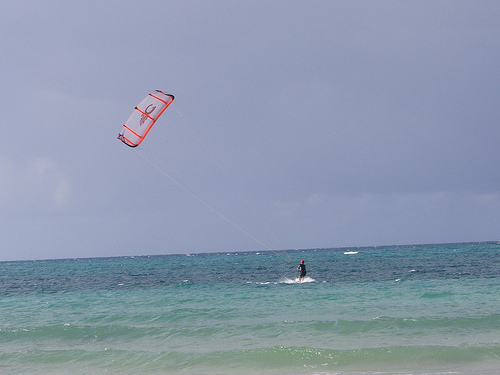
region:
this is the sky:
[41, 133, 86, 211]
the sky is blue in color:
[278, 88, 425, 167]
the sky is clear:
[236, 94, 470, 212]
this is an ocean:
[55, 255, 203, 356]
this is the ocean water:
[100, 260, 180, 280]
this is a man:
[290, 255, 315, 285]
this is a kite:
[110, 82, 176, 152]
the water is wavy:
[156, 290, 248, 350]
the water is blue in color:
[103, 262, 176, 287]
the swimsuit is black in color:
[300, 263, 305, 278]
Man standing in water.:
[298, 261, 306, 277]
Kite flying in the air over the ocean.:
[115, 88, 176, 150]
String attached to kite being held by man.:
[136, 146, 299, 276]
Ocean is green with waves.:
[37, 291, 494, 373]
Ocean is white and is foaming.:
[279, 277, 313, 282]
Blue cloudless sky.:
[222, 40, 449, 209]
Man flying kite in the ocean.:
[117, 87, 307, 280]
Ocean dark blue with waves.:
[11, 261, 206, 292]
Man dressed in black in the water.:
[296, 258, 306, 277]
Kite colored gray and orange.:
[113, 88, 175, 150]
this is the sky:
[216, 47, 296, 98]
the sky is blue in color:
[201, 26, 346, 126]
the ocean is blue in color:
[36, 260, 207, 317]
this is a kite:
[111, 77, 170, 168]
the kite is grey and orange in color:
[108, 67, 180, 212]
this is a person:
[269, 242, 331, 327]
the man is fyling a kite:
[106, 76, 323, 296]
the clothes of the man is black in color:
[287, 263, 315, 288]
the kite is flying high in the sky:
[107, 91, 207, 171]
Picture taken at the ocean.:
[17, 15, 490, 365]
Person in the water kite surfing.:
[278, 248, 329, 296]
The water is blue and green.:
[2, 258, 497, 370]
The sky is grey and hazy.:
[1, 23, 493, 253]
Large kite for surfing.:
[109, 73, 181, 158]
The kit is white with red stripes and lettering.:
[107, 74, 197, 167]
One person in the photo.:
[262, 241, 344, 288]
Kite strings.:
[142, 116, 307, 270]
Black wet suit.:
[292, 263, 319, 287]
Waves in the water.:
[0, 303, 490, 367]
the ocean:
[39, 211, 499, 368]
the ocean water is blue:
[2, 239, 489, 373]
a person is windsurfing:
[70, 71, 356, 301]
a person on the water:
[285, 258, 324, 285]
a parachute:
[110, 89, 192, 154]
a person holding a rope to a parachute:
[125, 78, 344, 294]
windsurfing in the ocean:
[117, 88, 434, 313]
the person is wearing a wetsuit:
[295, 260, 314, 285]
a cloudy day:
[7, 14, 499, 251]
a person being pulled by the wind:
[114, 79, 399, 339]